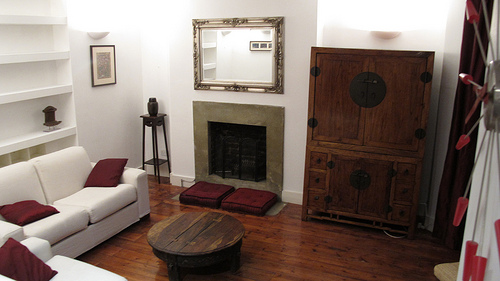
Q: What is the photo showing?
A: It is showing a living room.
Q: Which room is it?
A: It is a living room.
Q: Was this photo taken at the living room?
A: Yes, it was taken in the living room.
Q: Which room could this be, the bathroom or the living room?
A: It is the living room.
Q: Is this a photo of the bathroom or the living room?
A: It is showing the living room.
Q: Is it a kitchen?
A: No, it is a living room.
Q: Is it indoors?
A: Yes, it is indoors.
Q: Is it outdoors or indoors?
A: It is indoors.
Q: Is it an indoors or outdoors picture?
A: It is indoors.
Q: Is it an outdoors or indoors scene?
A: It is indoors.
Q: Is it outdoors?
A: No, it is indoors.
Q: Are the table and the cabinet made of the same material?
A: Yes, both the table and the cabinet are made of wood.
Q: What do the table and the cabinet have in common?
A: The material, both the table and the cabinet are wooden.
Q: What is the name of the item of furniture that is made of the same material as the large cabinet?
A: The piece of furniture is a table.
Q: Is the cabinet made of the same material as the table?
A: Yes, both the cabinet and the table are made of wood.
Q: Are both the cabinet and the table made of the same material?
A: Yes, both the cabinet and the table are made of wood.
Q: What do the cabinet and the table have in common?
A: The material, both the cabinet and the table are wooden.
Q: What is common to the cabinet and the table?
A: The material, both the cabinet and the table are wooden.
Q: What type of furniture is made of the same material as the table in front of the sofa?
A: The cabinet is made of the same material as the table.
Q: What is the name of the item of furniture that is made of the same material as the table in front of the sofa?
A: The piece of furniture is a cabinet.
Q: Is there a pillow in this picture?
A: Yes, there is a pillow.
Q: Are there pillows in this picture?
A: Yes, there is a pillow.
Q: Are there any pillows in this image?
A: Yes, there is a pillow.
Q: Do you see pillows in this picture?
A: Yes, there is a pillow.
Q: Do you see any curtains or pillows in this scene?
A: Yes, there is a pillow.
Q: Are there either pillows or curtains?
A: Yes, there is a pillow.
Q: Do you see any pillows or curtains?
A: Yes, there is a pillow.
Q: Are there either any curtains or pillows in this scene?
A: Yes, there is a pillow.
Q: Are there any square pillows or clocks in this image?
A: Yes, there is a square pillow.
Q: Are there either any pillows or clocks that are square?
A: Yes, the pillow is square.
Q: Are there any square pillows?
A: Yes, there is a square pillow.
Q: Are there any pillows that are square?
A: Yes, there is a pillow that is square.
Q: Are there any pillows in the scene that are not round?
A: Yes, there is a square pillow.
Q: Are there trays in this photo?
A: No, there are no trays.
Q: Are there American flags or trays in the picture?
A: No, there are no trays or American flags.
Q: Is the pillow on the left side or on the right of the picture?
A: The pillow is on the left of the image.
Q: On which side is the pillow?
A: The pillow is on the left of the image.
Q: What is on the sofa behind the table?
A: The pillow is on the sofa.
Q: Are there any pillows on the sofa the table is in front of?
A: Yes, there is a pillow on the sofa.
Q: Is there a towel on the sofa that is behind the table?
A: No, there is a pillow on the sofa.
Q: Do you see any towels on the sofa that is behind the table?
A: No, there is a pillow on the sofa.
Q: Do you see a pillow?
A: Yes, there is a pillow.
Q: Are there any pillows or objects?
A: Yes, there is a pillow.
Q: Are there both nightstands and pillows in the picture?
A: No, there is a pillow but no nightstands.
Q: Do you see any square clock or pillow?
A: Yes, there is a square pillow.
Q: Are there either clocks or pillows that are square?
A: Yes, the pillow is square.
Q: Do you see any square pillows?
A: Yes, there is a square pillow.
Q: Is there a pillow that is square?
A: Yes, there is a pillow that is square.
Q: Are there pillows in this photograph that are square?
A: Yes, there is a pillow that is square.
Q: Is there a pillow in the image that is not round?
A: Yes, there is a square pillow.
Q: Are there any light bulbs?
A: No, there are no light bulbs.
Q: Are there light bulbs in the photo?
A: No, there are no light bulbs.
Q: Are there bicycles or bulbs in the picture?
A: No, there are no bulbs or bicycles.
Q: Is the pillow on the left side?
A: Yes, the pillow is on the left of the image.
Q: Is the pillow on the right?
A: No, the pillow is on the left of the image.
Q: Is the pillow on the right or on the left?
A: The pillow is on the left of the image.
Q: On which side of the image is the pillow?
A: The pillow is on the left of the image.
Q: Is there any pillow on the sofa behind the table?
A: Yes, there is a pillow on the sofa.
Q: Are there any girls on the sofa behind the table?
A: No, there is a pillow on the sofa.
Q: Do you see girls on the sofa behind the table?
A: No, there is a pillow on the sofa.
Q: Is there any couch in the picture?
A: Yes, there is a couch.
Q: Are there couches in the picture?
A: Yes, there is a couch.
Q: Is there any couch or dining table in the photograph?
A: Yes, there is a couch.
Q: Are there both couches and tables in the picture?
A: Yes, there are both a couch and a table.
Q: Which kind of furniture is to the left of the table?
A: The piece of furniture is a couch.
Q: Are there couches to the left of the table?
A: Yes, there is a couch to the left of the table.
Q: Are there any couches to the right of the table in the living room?
A: No, the couch is to the left of the table.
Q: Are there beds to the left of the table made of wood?
A: No, there is a couch to the left of the table.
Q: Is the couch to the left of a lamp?
A: No, the couch is to the left of the table.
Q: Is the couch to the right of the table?
A: No, the couch is to the left of the table.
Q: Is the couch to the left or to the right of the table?
A: The couch is to the left of the table.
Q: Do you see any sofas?
A: Yes, there is a sofa.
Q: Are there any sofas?
A: Yes, there is a sofa.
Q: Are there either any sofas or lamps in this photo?
A: Yes, there is a sofa.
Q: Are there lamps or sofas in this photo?
A: Yes, there is a sofa.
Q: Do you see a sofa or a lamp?
A: Yes, there is a sofa.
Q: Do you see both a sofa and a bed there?
A: No, there is a sofa but no beds.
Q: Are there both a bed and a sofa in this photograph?
A: No, there is a sofa but no beds.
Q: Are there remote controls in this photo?
A: No, there are no remote controls.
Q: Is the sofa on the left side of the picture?
A: Yes, the sofa is on the left of the image.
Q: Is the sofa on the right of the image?
A: No, the sofa is on the left of the image.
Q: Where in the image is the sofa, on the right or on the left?
A: The sofa is on the left of the image.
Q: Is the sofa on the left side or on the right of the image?
A: The sofa is on the left of the image.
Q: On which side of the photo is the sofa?
A: The sofa is on the left of the image.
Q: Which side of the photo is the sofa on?
A: The sofa is on the left of the image.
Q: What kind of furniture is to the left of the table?
A: The piece of furniture is a sofa.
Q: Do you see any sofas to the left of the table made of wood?
A: Yes, there is a sofa to the left of the table.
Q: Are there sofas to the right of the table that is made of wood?
A: No, the sofa is to the left of the table.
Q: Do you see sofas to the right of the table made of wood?
A: No, the sofa is to the left of the table.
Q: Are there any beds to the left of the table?
A: No, there is a sofa to the left of the table.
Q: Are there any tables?
A: Yes, there is a table.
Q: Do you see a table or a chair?
A: Yes, there is a table.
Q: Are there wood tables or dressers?
A: Yes, there is a wood table.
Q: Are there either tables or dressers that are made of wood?
A: Yes, the table is made of wood.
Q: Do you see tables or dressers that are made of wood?
A: Yes, the table is made of wood.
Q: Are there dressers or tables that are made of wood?
A: Yes, the table is made of wood.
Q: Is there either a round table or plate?
A: Yes, there is a round table.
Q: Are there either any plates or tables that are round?
A: Yes, the table is round.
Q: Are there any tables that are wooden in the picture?
A: Yes, there is a wood table.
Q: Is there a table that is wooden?
A: Yes, there is a table that is wooden.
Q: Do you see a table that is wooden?
A: Yes, there is a table that is wooden.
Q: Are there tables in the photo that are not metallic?
A: Yes, there is a wooden table.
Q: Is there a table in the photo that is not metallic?
A: Yes, there is a wooden table.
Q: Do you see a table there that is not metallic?
A: Yes, there is a wooden table.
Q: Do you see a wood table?
A: Yes, there is a table that is made of wood.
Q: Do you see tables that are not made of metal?
A: Yes, there is a table that is made of wood.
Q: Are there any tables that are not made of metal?
A: Yes, there is a table that is made of wood.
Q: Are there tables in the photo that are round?
A: Yes, there is a round table.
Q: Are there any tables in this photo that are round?
A: Yes, there is a table that is round.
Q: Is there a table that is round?
A: Yes, there is a table that is round.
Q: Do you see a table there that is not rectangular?
A: Yes, there is a round table.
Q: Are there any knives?
A: No, there are no knives.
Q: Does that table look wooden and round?
A: Yes, the table is wooden and round.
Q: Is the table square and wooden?
A: No, the table is wooden but round.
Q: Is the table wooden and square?
A: No, the table is wooden but round.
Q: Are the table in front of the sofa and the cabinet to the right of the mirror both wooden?
A: Yes, both the table and the cabinet are wooden.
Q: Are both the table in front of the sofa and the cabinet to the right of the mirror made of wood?
A: Yes, both the table and the cabinet are made of wood.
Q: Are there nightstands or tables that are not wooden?
A: No, there is a table but it is wooden.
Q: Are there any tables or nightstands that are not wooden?
A: No, there is a table but it is wooden.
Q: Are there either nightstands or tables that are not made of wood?
A: No, there is a table but it is made of wood.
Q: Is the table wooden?
A: Yes, the table is wooden.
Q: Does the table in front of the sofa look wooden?
A: Yes, the table is wooden.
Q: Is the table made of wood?
A: Yes, the table is made of wood.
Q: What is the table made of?
A: The table is made of wood.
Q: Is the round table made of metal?
A: No, the table is made of wood.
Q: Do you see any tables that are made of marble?
A: No, there is a table but it is made of wood.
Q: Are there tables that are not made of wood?
A: No, there is a table but it is made of wood.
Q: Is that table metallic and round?
A: No, the table is round but wooden.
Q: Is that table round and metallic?
A: No, the table is round but wooden.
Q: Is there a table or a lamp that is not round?
A: No, there is a table but it is round.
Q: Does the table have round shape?
A: Yes, the table is round.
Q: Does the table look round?
A: Yes, the table is round.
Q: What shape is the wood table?
A: The table is round.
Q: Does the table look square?
A: No, the table is round.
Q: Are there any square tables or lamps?
A: No, there is a table but it is round.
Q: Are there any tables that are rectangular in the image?
A: No, there is a table but it is round.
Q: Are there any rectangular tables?
A: No, there is a table but it is round.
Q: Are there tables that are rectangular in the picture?
A: No, there is a table but it is round.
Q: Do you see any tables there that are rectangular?
A: No, there is a table but it is round.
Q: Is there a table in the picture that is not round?
A: No, there is a table but it is round.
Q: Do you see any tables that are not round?
A: No, there is a table but it is round.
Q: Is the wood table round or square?
A: The table is round.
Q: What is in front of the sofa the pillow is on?
A: The table is in front of the sofa.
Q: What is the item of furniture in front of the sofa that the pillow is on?
A: The piece of furniture is a table.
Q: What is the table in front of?
A: The table is in front of the sofa.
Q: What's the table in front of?
A: The table is in front of the sofa.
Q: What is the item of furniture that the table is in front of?
A: The piece of furniture is a sofa.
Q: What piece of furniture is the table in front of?
A: The table is in front of the sofa.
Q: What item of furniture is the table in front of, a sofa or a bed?
A: The table is in front of a sofa.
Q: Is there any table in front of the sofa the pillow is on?
A: Yes, there is a table in front of the sofa.